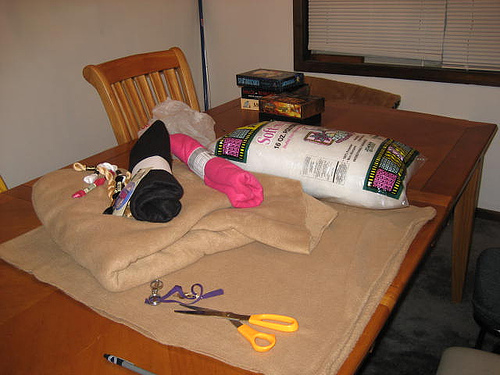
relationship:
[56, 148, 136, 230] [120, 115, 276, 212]
threads on fabric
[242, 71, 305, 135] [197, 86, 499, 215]
boxes on table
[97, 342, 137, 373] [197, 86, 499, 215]
pen on table